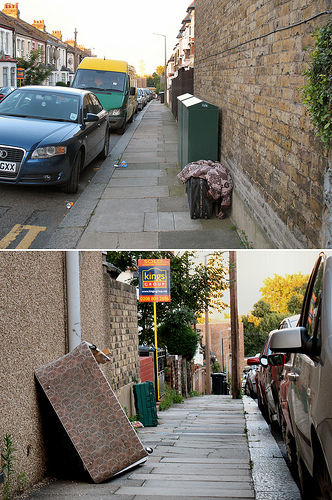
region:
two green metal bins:
[176, 92, 219, 171]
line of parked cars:
[0, 55, 155, 192]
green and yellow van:
[72, 56, 135, 129]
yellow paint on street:
[0, 222, 45, 248]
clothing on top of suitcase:
[179, 160, 232, 218]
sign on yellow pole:
[139, 258, 170, 404]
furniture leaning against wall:
[33, 342, 152, 483]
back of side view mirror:
[267, 328, 306, 354]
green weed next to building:
[2, 434, 26, 497]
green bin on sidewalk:
[132, 380, 157, 426]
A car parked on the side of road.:
[3, 78, 95, 196]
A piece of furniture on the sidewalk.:
[55, 341, 150, 487]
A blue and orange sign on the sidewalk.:
[126, 260, 196, 308]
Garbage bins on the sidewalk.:
[205, 366, 228, 396]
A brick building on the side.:
[220, 15, 313, 229]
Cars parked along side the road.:
[256, 334, 329, 416]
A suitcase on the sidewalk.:
[186, 173, 213, 219]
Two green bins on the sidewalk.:
[168, 82, 225, 166]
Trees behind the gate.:
[150, 252, 197, 344]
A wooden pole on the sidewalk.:
[219, 252, 245, 416]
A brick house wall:
[261, 147, 305, 206]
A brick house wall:
[119, 291, 143, 378]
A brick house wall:
[239, 141, 305, 231]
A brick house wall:
[216, 45, 255, 133]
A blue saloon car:
[1, 87, 83, 197]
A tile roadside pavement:
[153, 426, 220, 488]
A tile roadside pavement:
[181, 382, 228, 420]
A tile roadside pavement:
[89, 186, 177, 240]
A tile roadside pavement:
[120, 134, 182, 187]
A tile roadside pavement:
[148, 100, 170, 141]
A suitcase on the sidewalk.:
[170, 175, 209, 228]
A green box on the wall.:
[127, 373, 163, 423]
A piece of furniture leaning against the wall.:
[32, 334, 153, 477]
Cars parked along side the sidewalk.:
[246, 316, 331, 438]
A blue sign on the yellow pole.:
[128, 256, 177, 311]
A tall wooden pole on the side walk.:
[221, 261, 254, 396]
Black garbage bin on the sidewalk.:
[204, 350, 220, 495]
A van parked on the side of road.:
[6, 32, 135, 127]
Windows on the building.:
[13, 37, 46, 63]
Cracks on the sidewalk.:
[192, 412, 233, 482]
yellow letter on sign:
[143, 258, 147, 264]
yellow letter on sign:
[146, 257, 151, 265]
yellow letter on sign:
[152, 258, 156, 264]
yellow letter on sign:
[156, 259, 163, 263]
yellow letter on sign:
[143, 272, 149, 280]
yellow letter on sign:
[148, 275, 152, 280]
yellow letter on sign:
[151, 272, 156, 281]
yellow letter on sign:
[156, 273, 160, 280]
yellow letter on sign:
[159, 271, 165, 279]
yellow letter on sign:
[149, 296, 154, 301]